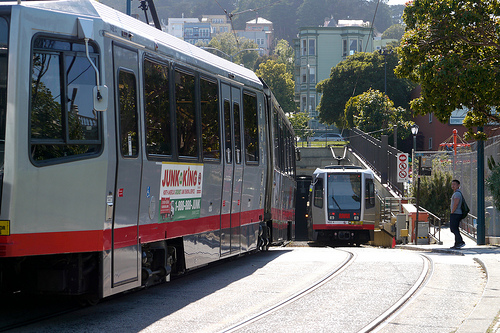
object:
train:
[306, 160, 383, 248]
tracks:
[286, 241, 434, 333]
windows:
[239, 87, 262, 168]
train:
[2, 0, 305, 325]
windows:
[199, 77, 227, 163]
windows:
[171, 65, 204, 158]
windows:
[135, 52, 177, 159]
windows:
[111, 68, 148, 158]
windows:
[23, 30, 105, 167]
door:
[102, 35, 153, 295]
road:
[37, 232, 490, 331]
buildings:
[296, 20, 380, 143]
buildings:
[242, 13, 274, 58]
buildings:
[178, 20, 215, 53]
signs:
[397, 154, 408, 162]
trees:
[287, 108, 310, 140]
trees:
[202, 28, 257, 70]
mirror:
[92, 83, 110, 115]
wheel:
[355, 240, 361, 247]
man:
[444, 176, 470, 251]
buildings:
[164, 12, 193, 42]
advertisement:
[153, 162, 207, 221]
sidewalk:
[428, 221, 500, 332]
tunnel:
[287, 140, 419, 249]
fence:
[345, 117, 417, 204]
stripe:
[312, 220, 376, 231]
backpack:
[459, 197, 471, 221]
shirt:
[448, 191, 466, 216]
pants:
[448, 211, 470, 246]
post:
[410, 155, 433, 244]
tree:
[314, 38, 419, 144]